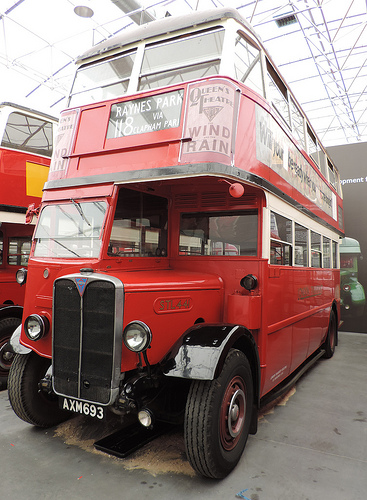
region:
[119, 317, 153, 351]
circular headlight on front of red bus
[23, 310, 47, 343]
circular headlight on front of red bus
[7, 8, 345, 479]
double decker red bus sitting on pavement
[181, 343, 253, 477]
black tire on side of red bus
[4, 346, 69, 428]
black tire on side of red bus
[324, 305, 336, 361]
black tire on side of red bus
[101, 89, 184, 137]
headsign on red bus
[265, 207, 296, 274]
window on side of red bus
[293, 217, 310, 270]
window on side of red bus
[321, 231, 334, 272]
window on side of red bus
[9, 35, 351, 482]
large double decker bus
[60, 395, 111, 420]
black and white license plate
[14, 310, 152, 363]
two circualr lights on the front of the bus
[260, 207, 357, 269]
row of windows on the side of the bus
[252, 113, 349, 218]
advertisement on the side of the bus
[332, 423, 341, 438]
tar mark on the ground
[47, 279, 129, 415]
vent on the front of the vehicle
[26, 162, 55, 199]
yellow paint on the side of the bus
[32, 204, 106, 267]
reflection on the window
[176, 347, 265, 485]
large front wheel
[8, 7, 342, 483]
red, black, white and gray double decker bus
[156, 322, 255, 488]
left front wheel with shiny black fender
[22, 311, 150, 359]
headlights of a red double decker bus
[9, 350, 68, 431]
right front wheel of a red bus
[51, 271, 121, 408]
front grill of a red double decker bus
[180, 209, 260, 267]
front windshield of a red bus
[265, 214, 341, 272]
windows along lower section of bus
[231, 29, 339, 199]
windows in upper section of bus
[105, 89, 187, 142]
black sign with white destination text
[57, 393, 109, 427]
black and white license of red bus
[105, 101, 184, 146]
a black and white marquee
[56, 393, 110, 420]
a black and white license plate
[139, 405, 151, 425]
a shiny round headlight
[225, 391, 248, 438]
a gray hubcap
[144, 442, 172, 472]
saw dust under the bus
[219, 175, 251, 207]
a red side view mirror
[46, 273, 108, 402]
a black grille on the truck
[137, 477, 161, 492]
oil spots on the street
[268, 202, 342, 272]
windows in the bus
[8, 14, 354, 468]
a large double decker bus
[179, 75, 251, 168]
sign on double decker bus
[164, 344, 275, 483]
right wheel on bus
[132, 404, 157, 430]
light on bus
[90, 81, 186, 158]
sign of where bus went Raynes Park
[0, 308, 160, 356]
two headlights on bus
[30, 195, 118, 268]
window of double decker bus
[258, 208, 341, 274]
many windows in double decker bus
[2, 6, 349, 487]
two double decker buses parked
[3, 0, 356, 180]
top of double decker bus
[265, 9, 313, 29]
vent in ceiling where double decker bus is parked